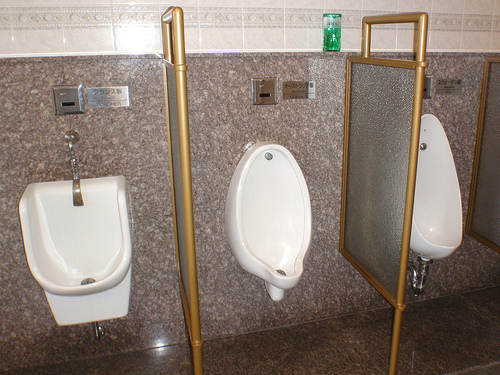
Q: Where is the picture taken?
A: A bathroom.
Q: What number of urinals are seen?
A: 3.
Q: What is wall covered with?
A: Tile.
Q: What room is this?
A: Man's room.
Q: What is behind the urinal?
A: Granite wall.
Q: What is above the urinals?
A: Tiles.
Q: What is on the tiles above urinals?
A: Design.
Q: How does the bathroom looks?
A: Clean.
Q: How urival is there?
A: Three.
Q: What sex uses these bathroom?
A: Male.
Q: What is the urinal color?
A: White.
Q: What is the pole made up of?
A: Gold.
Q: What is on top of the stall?
A: Soap.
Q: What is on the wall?
A: A urinal.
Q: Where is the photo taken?
A: Bathroom.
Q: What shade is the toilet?
A: White.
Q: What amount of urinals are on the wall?
A: Three.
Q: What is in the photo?
A: Urinal.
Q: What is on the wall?
A: A urinal.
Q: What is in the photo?
A: Round urinal.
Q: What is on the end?
A: Long urinal.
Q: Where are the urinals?
A: Wall.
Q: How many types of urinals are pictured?
A: Three.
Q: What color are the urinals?
A: White.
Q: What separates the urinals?
A: Textured glass.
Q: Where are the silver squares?
A: Top of the urinals.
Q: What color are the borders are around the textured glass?
A: Bronze.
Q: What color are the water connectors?
A: Silver.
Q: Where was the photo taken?
A: In a bathroom.